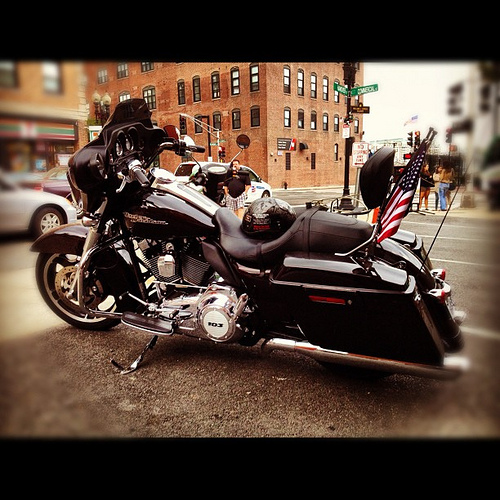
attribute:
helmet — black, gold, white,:
[241, 196, 298, 238]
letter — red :
[252, 226, 255, 231]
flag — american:
[381, 163, 429, 233]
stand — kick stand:
[106, 340, 166, 377]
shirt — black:
[416, 170, 434, 184]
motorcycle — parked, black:
[33, 77, 482, 409]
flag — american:
[375, 140, 427, 242]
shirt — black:
[212, 170, 255, 198]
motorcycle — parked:
[35, 134, 477, 395]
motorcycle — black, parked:
[29, 97, 469, 377]